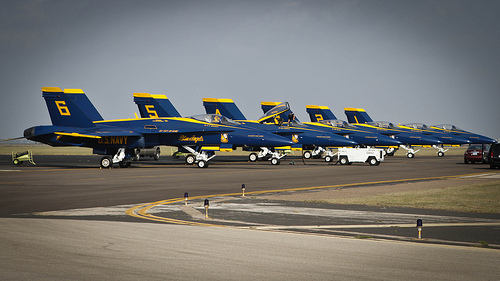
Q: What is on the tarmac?
A: Blue and Yellow jets.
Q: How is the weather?
A: Hazy skies.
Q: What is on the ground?
A: Wheels for the jets.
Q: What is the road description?
A: Gray asphalt.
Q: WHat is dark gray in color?
A: The road.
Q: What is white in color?
A: The landing gear.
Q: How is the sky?
A: Clear.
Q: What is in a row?
A: The airplanes.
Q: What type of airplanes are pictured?
A: Navy airplanes.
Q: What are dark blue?
A: The airplanes.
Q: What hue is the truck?
A: White.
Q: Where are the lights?
A: On the runway.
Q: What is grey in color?
A: The sky.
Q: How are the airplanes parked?
A: In a row.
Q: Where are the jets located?
A: On the tarmac.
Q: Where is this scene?
A: Airport.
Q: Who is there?
A: No one.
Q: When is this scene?
A: Daytime.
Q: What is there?
A: Airplanes.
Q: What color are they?
A: Blue and yellow.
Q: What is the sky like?
A: Clear.